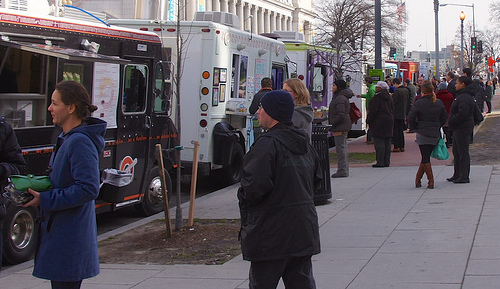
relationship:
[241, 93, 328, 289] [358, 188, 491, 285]
man on sidewalk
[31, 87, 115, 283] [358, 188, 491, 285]
woman on sidewalk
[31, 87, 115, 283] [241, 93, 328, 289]
woman near man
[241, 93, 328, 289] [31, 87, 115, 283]
man near woman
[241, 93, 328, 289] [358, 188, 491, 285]
man in sidewalk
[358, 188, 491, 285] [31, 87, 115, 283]
sidewalk below woman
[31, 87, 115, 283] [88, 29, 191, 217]
woman near truck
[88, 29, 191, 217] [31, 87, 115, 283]
truck near woman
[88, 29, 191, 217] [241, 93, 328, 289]
truck near man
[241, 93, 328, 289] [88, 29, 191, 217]
man near truck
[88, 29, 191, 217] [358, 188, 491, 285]
truck near sidewalk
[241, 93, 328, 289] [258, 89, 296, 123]
man wearing cap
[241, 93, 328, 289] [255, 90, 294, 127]
man has head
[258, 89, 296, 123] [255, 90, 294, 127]
cap on head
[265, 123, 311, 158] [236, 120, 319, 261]
hoodie on jacket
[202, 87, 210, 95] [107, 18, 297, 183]
light on food truck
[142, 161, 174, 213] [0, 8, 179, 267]
wheel at front of truck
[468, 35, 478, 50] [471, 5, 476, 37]
traffic signal on pole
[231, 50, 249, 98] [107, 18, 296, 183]
window on side of food truck